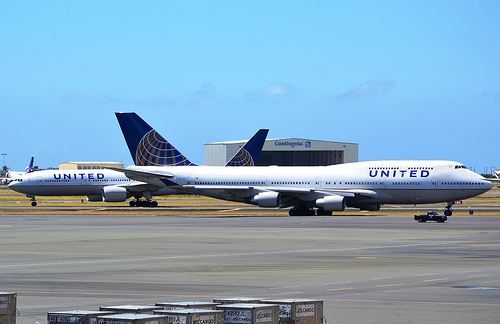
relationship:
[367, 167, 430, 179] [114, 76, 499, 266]
logo on airplane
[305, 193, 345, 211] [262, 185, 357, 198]
engine under wing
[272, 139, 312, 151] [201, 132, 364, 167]
logo on building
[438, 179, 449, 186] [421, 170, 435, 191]
window next to door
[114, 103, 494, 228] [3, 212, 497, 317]
plane on tarmac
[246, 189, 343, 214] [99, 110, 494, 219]
jet engine on plane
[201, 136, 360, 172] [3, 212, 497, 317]
airplane on tarmac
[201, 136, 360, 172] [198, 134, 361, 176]
airplane beside hangar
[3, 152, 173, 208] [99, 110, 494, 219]
plane near plane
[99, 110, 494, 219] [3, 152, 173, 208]
plane near plane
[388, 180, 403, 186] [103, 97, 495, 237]
window on plane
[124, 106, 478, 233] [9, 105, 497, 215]
plane on background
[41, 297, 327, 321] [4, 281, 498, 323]
carts on foreground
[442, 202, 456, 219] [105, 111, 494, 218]
wheel on airplane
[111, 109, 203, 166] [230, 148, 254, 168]
tail wing has globe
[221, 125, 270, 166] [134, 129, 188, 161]
tail wing has globe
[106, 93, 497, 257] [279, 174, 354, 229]
plane has engine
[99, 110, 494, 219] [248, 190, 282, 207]
plane has engine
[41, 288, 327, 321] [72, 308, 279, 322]
carts handling food